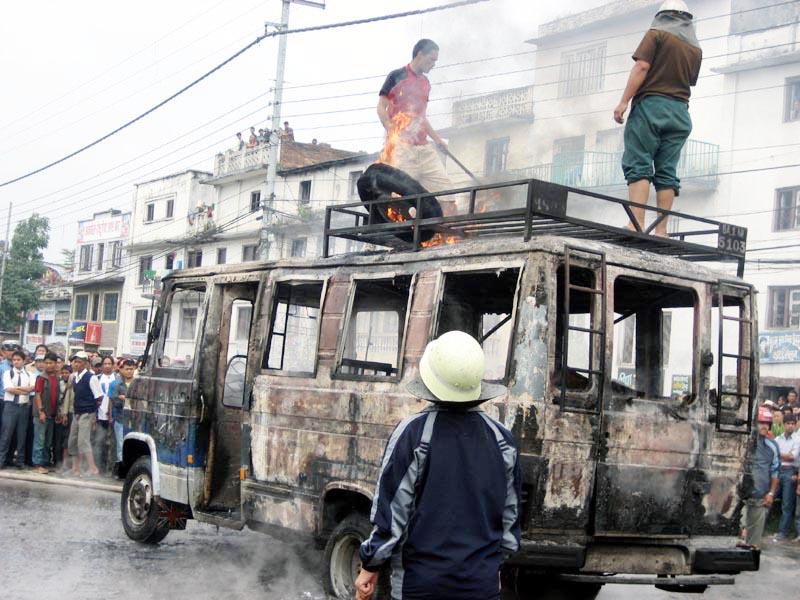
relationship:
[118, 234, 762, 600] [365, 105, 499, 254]
car burning fire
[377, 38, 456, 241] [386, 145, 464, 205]
man wearing khaki pants shorts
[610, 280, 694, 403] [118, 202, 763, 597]
window on car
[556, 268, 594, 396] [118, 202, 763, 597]
window on car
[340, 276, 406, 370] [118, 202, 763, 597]
window on car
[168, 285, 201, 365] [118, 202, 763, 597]
window on car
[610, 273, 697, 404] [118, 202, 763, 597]
window on car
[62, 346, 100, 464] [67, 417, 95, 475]
person wearing pants